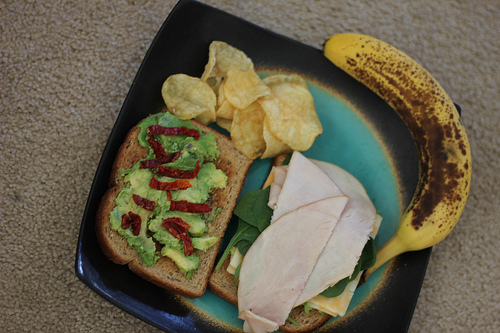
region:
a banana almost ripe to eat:
[313, 37, 475, 287]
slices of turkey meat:
[207, 132, 399, 332]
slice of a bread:
[95, 118, 247, 290]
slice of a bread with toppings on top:
[197, 171, 402, 328]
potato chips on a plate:
[157, 27, 324, 163]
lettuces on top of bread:
[89, 109, 269, 289]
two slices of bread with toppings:
[81, 102, 432, 329]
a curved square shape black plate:
[64, 8, 470, 331]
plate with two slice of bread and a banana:
[63, 7, 473, 327]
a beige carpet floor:
[9, 48, 89, 141]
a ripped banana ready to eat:
[306, 24, 473, 279]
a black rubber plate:
[73, 2, 458, 330]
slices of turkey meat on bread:
[225, 152, 394, 331]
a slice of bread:
[88, 107, 264, 295]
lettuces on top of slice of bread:
[89, 99, 271, 292]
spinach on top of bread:
[204, 174, 386, 298]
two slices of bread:
[75, 101, 392, 331]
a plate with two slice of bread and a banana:
[69, 3, 475, 331]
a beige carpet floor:
[6, 15, 116, 114]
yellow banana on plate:
[341, 46, 462, 287]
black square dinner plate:
[93, 28, 481, 328]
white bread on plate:
[102, 68, 211, 328]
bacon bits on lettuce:
[112, 163, 204, 213]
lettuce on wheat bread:
[104, 60, 253, 267]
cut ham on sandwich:
[213, 120, 356, 323]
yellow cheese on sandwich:
[245, 205, 392, 320]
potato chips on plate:
[205, 45, 338, 144]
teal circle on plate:
[250, 108, 407, 192]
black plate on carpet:
[21, 23, 343, 328]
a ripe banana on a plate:
[310, 26, 472, 295]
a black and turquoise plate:
[76, 3, 454, 328]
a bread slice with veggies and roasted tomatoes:
[86, 95, 250, 304]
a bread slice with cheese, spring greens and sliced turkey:
[214, 149, 381, 329]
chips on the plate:
[157, 31, 324, 171]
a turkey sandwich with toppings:
[87, 88, 377, 325]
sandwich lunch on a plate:
[82, 2, 464, 327]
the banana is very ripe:
[310, 24, 476, 271]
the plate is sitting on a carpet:
[2, 13, 497, 331]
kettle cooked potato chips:
[158, 35, 323, 161]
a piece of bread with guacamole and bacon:
[96, 114, 249, 297]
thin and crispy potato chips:
[161, 40, 324, 154]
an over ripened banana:
[320, 29, 470, 285]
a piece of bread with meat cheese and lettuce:
[205, 158, 378, 328]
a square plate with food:
[74, 0, 470, 332]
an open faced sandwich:
[101, 111, 375, 326]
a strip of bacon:
[147, 123, 204, 139]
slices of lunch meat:
[241, 155, 373, 329]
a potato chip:
[161, 70, 218, 122]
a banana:
[327, 37, 469, 283]